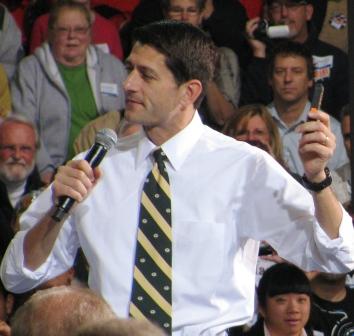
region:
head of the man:
[89, 13, 230, 138]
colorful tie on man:
[96, 155, 198, 310]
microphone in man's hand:
[22, 127, 129, 230]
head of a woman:
[243, 258, 327, 334]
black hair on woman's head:
[257, 254, 322, 296]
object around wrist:
[280, 147, 345, 208]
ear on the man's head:
[161, 56, 222, 124]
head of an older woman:
[20, 5, 107, 85]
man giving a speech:
[1, 3, 352, 333]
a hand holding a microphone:
[41, 117, 120, 243]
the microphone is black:
[42, 122, 122, 235]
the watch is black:
[297, 163, 335, 194]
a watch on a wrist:
[298, 162, 338, 198]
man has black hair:
[247, 252, 322, 334]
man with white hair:
[1, 111, 50, 203]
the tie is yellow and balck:
[128, 143, 180, 333]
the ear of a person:
[178, 74, 207, 112]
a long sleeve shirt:
[2, 113, 352, 334]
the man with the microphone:
[2, 19, 353, 335]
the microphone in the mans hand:
[53, 123, 118, 221]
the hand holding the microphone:
[51, 158, 104, 208]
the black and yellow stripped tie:
[129, 145, 174, 334]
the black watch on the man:
[301, 166, 333, 193]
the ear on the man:
[184, 79, 202, 109]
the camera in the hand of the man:
[252, 16, 289, 40]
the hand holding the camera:
[245, 15, 265, 58]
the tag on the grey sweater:
[97, 81, 118, 94]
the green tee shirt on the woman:
[56, 62, 101, 161]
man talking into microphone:
[2, 16, 353, 335]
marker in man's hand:
[301, 78, 328, 149]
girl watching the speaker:
[246, 262, 321, 334]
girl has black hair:
[253, 256, 316, 302]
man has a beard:
[0, 155, 36, 184]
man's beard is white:
[2, 157, 35, 183]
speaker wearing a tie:
[121, 148, 181, 334]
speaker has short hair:
[132, 14, 217, 114]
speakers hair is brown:
[131, 15, 216, 113]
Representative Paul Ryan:
[1, 21, 352, 335]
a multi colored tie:
[127, 148, 173, 335]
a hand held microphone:
[51, 126, 116, 223]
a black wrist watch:
[301, 165, 332, 192]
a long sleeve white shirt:
[0, 107, 353, 335]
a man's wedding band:
[322, 135, 329, 144]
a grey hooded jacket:
[10, 39, 129, 176]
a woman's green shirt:
[53, 62, 96, 155]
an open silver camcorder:
[254, 15, 286, 39]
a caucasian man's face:
[120, 23, 214, 128]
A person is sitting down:
[228, 108, 276, 150]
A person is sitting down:
[241, 268, 310, 332]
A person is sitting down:
[306, 255, 352, 334]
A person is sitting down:
[259, 46, 346, 186]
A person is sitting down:
[252, 6, 342, 127]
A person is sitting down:
[14, 2, 132, 159]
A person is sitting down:
[0, 118, 48, 209]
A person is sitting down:
[17, 280, 65, 332]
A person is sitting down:
[80, 306, 152, 334]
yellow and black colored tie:
[128, 148, 178, 335]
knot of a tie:
[147, 147, 167, 165]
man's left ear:
[179, 75, 204, 112]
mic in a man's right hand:
[44, 123, 121, 220]